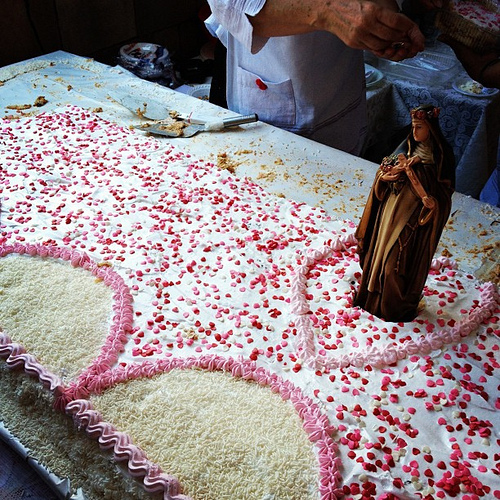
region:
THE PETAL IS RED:
[464, 460, 469, 491]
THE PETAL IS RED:
[459, 473, 467, 483]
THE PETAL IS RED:
[449, 467, 450, 489]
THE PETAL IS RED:
[469, 465, 470, 482]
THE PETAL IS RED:
[454, 468, 464, 484]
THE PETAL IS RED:
[456, 475, 459, 491]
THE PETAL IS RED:
[451, 471, 456, 492]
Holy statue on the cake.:
[353, 98, 446, 329]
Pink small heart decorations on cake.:
[1, 53, 492, 493]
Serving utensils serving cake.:
[113, 79, 266, 141]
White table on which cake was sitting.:
[3, 50, 496, 498]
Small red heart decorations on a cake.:
[3, 49, 497, 497]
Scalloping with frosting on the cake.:
[6, 332, 201, 498]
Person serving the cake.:
[196, 0, 491, 161]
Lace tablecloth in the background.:
[355, 54, 499, 191]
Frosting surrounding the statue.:
[287, 210, 499, 365]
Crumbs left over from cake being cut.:
[1, 41, 498, 273]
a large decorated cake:
[9, 103, 497, 492]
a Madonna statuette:
[339, 99, 449, 323]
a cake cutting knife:
[93, 80, 222, 135]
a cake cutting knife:
[132, 107, 266, 140]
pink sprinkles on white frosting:
[7, 122, 142, 233]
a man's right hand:
[236, 3, 423, 63]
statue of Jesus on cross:
[386, 146, 438, 208]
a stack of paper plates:
[118, 39, 168, 85]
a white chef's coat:
[202, 0, 369, 131]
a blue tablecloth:
[376, 54, 498, 196]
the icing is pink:
[131, 458, 148, 483]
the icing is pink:
[122, 435, 137, 481]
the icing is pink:
[154, 470, 161, 498]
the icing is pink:
[151, 479, 169, 498]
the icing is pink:
[159, 469, 168, 491]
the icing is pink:
[160, 480, 172, 491]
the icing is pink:
[149, 481, 167, 489]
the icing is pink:
[156, 476, 181, 488]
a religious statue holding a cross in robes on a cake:
[339, 88, 477, 328]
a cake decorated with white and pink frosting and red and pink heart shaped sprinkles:
[0, 108, 499, 498]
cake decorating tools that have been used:
[96, 75, 286, 153]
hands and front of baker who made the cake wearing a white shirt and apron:
[204, 0, 429, 154]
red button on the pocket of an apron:
[230, 60, 297, 130]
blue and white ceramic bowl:
[107, 22, 193, 83]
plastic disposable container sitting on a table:
[373, 40, 463, 87]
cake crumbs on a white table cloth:
[221, 124, 354, 202]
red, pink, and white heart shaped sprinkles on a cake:
[341, 379, 485, 474]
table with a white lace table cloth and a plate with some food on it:
[397, 72, 492, 126]